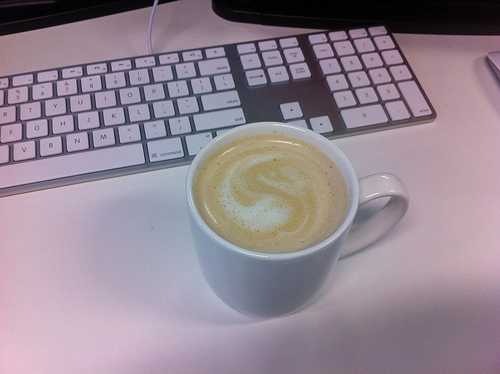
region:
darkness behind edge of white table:
[0, 2, 165, 38]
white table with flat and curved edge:
[0, 1, 495, 367]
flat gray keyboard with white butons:
[0, 21, 435, 196]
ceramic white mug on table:
[185, 90, 410, 315]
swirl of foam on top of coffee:
[185, 121, 360, 256]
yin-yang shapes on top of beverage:
[191, 115, 353, 252]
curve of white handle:
[337, 172, 409, 257]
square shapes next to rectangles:
[112, 86, 243, 136]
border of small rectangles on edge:
[0, 35, 225, 85]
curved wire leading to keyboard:
[137, 0, 168, 51]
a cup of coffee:
[181, 131, 404, 321]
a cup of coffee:
[174, 118, 391, 330]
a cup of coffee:
[180, 114, 394, 332]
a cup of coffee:
[170, 128, 387, 307]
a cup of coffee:
[187, 115, 388, 363]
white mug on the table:
[190, 127, 385, 329]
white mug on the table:
[168, 119, 420, 348]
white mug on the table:
[165, 121, 418, 341]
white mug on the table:
[168, 132, 384, 327]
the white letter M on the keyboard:
[93, 127, 114, 147]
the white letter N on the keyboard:
[65, 131, 87, 151]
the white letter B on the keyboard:
[40, 137, 59, 154]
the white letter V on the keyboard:
[12, 140, 33, 160]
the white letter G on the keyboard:
[27, 118, 47, 137]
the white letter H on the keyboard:
[52, 116, 73, 132]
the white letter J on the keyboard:
[77, 111, 99, 130]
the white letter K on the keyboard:
[103, 108, 123, 123]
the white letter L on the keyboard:
[130, 102, 150, 122]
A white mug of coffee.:
[185, 121, 408, 317]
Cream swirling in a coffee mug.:
[194, 135, 351, 253]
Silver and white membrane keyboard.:
[0, 23, 435, 195]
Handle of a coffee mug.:
[336, 173, 408, 261]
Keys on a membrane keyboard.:
[240, 36, 310, 86]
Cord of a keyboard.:
[143, 0, 161, 52]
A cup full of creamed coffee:
[183, 121, 407, 318]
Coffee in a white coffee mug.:
[197, 139, 350, 250]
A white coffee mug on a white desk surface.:
[186, 121, 408, 323]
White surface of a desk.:
[6, 212, 189, 356]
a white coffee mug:
[183, 120, 408, 316]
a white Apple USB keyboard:
[1, 20, 437, 196]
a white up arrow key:
[279, 100, 303, 119]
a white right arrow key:
[310, 114, 332, 134]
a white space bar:
[1, 141, 147, 188]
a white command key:
[146, 135, 183, 163]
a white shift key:
[191, 105, 246, 130]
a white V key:
[12, 140, 36, 161]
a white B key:
[38, 135, 61, 155]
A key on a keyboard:
[245, 68, 264, 84]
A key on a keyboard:
[289, 63, 311, 79]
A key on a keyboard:
[334, 91, 356, 106]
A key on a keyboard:
[345, 69, 372, 85]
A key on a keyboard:
[6, 84, 26, 104]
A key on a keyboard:
[32, 81, 52, 101]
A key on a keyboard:
[56, 79, 78, 96]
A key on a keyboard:
[80, 73, 102, 92]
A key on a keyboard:
[106, 70, 125, 87]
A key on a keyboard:
[129, 67, 149, 84]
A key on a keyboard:
[151, 64, 173, 81]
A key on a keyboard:
[175, 60, 197, 79]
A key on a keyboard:
[196, 56, 230, 78]